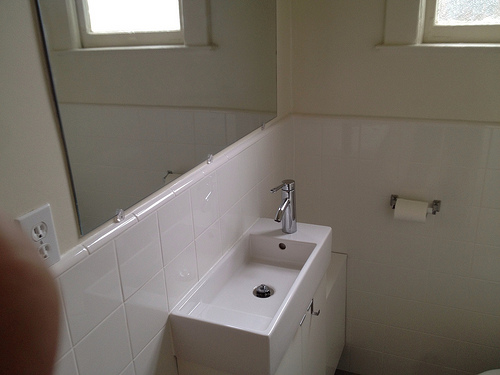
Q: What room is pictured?
A: It is a bathroom.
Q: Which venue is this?
A: This is a bathroom.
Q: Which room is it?
A: It is a bathroom.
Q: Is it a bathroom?
A: Yes, it is a bathroom.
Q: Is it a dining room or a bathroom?
A: It is a bathroom.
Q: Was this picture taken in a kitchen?
A: No, the picture was taken in a bathroom.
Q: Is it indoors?
A: Yes, it is indoors.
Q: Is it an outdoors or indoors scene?
A: It is indoors.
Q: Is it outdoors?
A: No, it is indoors.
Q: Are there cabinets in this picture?
A: Yes, there is a cabinet.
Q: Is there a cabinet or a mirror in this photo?
A: Yes, there is a cabinet.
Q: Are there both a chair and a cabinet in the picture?
A: No, there is a cabinet but no chairs.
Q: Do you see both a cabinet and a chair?
A: No, there is a cabinet but no chairs.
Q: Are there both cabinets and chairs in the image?
A: No, there is a cabinet but no chairs.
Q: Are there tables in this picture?
A: No, there are no tables.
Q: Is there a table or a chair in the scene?
A: No, there are no tables or chairs.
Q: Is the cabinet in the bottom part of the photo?
A: Yes, the cabinet is in the bottom of the image.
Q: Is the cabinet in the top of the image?
A: No, the cabinet is in the bottom of the image.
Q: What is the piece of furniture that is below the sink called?
A: The piece of furniture is a cabinet.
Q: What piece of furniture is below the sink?
A: The piece of furniture is a cabinet.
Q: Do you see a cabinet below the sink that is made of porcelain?
A: Yes, there is a cabinet below the sink.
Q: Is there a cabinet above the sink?
A: No, the cabinet is below the sink.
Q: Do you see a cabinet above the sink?
A: No, the cabinet is below the sink.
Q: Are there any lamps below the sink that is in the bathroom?
A: No, there is a cabinet below the sink.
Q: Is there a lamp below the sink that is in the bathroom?
A: No, there is a cabinet below the sink.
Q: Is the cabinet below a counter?
A: No, the cabinet is below the sink.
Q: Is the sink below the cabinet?
A: No, the cabinet is below the sink.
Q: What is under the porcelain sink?
A: The cabinet is under the sink.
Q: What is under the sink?
A: The cabinet is under the sink.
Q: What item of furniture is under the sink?
A: The piece of furniture is a cabinet.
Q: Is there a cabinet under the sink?
A: Yes, there is a cabinet under the sink.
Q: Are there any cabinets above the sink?
A: No, the cabinet is under the sink.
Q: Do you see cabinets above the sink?
A: No, the cabinet is under the sink.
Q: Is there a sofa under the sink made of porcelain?
A: No, there is a cabinet under the sink.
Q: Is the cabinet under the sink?
A: Yes, the cabinet is under the sink.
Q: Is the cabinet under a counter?
A: No, the cabinet is under the sink.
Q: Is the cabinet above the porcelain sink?
A: No, the cabinet is under the sink.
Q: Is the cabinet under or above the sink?
A: The cabinet is under the sink.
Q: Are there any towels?
A: No, there are no towels.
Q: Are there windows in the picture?
A: Yes, there is a window.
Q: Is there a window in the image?
A: Yes, there is a window.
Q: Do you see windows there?
A: Yes, there is a window.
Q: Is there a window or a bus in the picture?
A: Yes, there is a window.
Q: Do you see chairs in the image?
A: No, there are no chairs.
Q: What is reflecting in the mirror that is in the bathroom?
A: The window is reflecting in the mirror.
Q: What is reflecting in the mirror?
A: The window is reflecting in the mirror.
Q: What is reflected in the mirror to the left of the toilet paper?
A: The window is reflected in the mirror.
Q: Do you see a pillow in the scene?
A: No, there are no pillows.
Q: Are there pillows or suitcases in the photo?
A: No, there are no pillows or suitcases.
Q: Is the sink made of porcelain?
A: Yes, the sink is made of porcelain.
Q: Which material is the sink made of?
A: The sink is made of porcelain.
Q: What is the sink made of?
A: The sink is made of porcelain.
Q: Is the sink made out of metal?
A: No, the sink is made of porcelain.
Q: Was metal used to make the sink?
A: No, the sink is made of porcelain.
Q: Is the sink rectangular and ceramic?
A: Yes, the sink is rectangular and ceramic.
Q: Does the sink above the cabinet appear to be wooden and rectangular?
A: No, the sink is rectangular but ceramic.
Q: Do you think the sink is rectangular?
A: Yes, the sink is rectangular.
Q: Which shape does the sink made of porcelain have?
A: The sink has rectangular shape.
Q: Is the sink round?
A: No, the sink is rectangular.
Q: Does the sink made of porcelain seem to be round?
A: No, the sink is rectangular.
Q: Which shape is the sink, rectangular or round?
A: The sink is rectangular.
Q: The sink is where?
A: The sink is in the bathroom.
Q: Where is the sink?
A: The sink is in the bathroom.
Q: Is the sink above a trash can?
A: No, the sink is above a cabinet.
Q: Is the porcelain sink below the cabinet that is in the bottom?
A: No, the sink is above the cabinet.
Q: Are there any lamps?
A: No, there are no lamps.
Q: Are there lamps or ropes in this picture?
A: No, there are no lamps or ropes.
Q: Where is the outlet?
A: The outlet is in the bathroom.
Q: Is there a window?
A: Yes, there is a window.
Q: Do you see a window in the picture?
A: Yes, there is a window.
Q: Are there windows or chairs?
A: Yes, there is a window.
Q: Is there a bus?
A: No, there are no buses.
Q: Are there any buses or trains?
A: No, there are no buses or trains.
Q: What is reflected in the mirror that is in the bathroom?
A: The window is reflected in the mirror.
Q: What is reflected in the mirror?
A: The window is reflected in the mirror.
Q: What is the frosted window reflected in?
A: The window is reflected in the mirror.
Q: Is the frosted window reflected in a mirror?
A: Yes, the window is reflected in a mirror.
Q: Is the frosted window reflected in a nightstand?
A: No, the window is reflected in a mirror.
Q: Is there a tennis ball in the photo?
A: No, there are no tennis balls.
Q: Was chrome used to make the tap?
A: Yes, the tap is made of chrome.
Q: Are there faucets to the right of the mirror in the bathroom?
A: Yes, there is a faucet to the right of the mirror.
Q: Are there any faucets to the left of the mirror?
A: No, the faucet is to the right of the mirror.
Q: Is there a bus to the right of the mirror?
A: No, there is a faucet to the right of the mirror.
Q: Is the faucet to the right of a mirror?
A: Yes, the faucet is to the right of a mirror.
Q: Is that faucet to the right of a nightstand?
A: No, the faucet is to the right of a mirror.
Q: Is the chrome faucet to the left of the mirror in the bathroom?
A: No, the tap is to the right of the mirror.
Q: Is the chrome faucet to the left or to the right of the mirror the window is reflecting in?
A: The tap is to the right of the mirror.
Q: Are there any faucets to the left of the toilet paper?
A: Yes, there is a faucet to the left of the toilet paper.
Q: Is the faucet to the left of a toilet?
A: No, the faucet is to the left of the toilet paper.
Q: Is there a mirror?
A: Yes, there is a mirror.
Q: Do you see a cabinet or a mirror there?
A: Yes, there is a mirror.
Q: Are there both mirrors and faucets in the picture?
A: Yes, there are both a mirror and a faucet.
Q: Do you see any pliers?
A: No, there are no pliers.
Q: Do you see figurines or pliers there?
A: No, there are no pliers or figurines.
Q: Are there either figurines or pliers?
A: No, there are no pliers or figurines.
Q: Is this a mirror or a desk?
A: This is a mirror.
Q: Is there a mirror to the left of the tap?
A: Yes, there is a mirror to the left of the tap.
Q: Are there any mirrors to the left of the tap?
A: Yes, there is a mirror to the left of the tap.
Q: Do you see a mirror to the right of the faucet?
A: No, the mirror is to the left of the faucet.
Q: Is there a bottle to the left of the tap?
A: No, there is a mirror to the left of the tap.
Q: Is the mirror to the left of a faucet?
A: Yes, the mirror is to the left of a faucet.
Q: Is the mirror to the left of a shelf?
A: No, the mirror is to the left of a faucet.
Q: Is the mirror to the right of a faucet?
A: No, the mirror is to the left of a faucet.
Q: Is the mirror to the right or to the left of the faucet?
A: The mirror is to the left of the faucet.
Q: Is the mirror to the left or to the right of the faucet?
A: The mirror is to the left of the faucet.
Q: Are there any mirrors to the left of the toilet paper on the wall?
A: Yes, there is a mirror to the left of the toilet paper.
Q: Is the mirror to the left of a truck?
A: No, the mirror is to the left of the toilet paper.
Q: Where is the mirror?
A: The mirror is in the bathroom.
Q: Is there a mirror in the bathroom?
A: Yes, there is a mirror in the bathroom.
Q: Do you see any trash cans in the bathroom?
A: No, there is a mirror in the bathroom.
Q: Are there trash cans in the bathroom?
A: No, there is a mirror in the bathroom.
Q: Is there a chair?
A: No, there are no chairs.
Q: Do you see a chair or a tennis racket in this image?
A: No, there are no chairs or rackets.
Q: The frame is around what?
A: The frame is around the window.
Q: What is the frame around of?
A: The frame is around the window.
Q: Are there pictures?
A: No, there are no pictures.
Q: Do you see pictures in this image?
A: No, there are no pictures.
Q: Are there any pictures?
A: No, there are no pictures.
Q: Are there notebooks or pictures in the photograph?
A: No, there are no pictures or notebooks.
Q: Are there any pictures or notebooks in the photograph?
A: No, there are no pictures or notebooks.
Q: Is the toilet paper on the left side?
A: No, the toilet paper is on the right of the image.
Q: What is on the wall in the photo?
A: The toilet paper is on the wall.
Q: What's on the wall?
A: The toilet paper is on the wall.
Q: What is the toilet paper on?
A: The toilet paper is on the wall.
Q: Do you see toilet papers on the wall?
A: Yes, there is a toilet paper on the wall.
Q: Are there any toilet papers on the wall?
A: Yes, there is a toilet paper on the wall.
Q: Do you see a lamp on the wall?
A: No, there is a toilet paper on the wall.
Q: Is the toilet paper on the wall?
A: Yes, the toilet paper is on the wall.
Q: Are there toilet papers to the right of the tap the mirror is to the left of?
A: Yes, there is a toilet paper to the right of the faucet.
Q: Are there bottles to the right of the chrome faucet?
A: No, there is a toilet paper to the right of the tap.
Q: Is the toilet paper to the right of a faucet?
A: Yes, the toilet paper is to the right of a faucet.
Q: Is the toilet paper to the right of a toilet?
A: No, the toilet paper is to the right of a faucet.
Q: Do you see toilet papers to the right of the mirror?
A: Yes, there is a toilet paper to the right of the mirror.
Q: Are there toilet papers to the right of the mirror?
A: Yes, there is a toilet paper to the right of the mirror.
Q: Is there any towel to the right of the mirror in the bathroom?
A: No, there is a toilet paper to the right of the mirror.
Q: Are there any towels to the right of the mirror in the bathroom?
A: No, there is a toilet paper to the right of the mirror.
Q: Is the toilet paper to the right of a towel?
A: No, the toilet paper is to the right of the mirror.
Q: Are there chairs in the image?
A: No, there are no chairs.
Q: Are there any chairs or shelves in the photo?
A: No, there are no chairs or shelves.